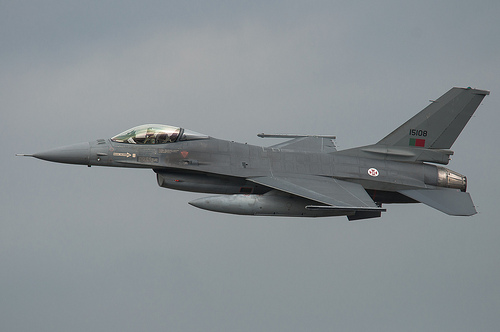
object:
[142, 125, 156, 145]
pilot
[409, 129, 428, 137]
numbers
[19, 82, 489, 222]
aircraft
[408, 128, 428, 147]
markings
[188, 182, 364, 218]
missile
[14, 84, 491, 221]
plane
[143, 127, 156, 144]
person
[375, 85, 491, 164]
tail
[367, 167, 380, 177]
symbol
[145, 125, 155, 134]
helmet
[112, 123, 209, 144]
cockpit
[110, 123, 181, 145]
glass